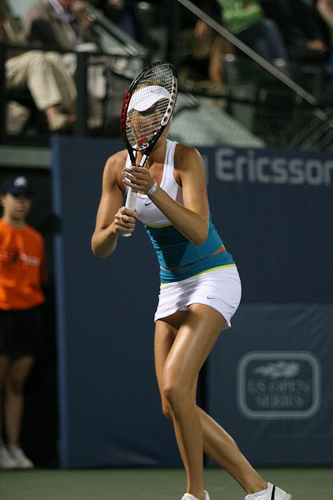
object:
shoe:
[244, 483, 293, 500]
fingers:
[115, 206, 140, 237]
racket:
[120, 59, 179, 238]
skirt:
[153, 265, 242, 331]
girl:
[0, 170, 50, 474]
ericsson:
[214, 147, 333, 188]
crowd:
[0, 0, 134, 143]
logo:
[236, 352, 323, 424]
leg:
[160, 303, 225, 495]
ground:
[301, 470, 323, 500]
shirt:
[124, 137, 236, 287]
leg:
[154, 284, 267, 494]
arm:
[144, 171, 210, 247]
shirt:
[0, 216, 47, 310]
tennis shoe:
[178, 489, 210, 498]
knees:
[162, 367, 181, 407]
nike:
[144, 200, 153, 208]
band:
[145, 179, 159, 197]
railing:
[0, 43, 332, 147]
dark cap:
[0, 173, 33, 196]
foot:
[244, 481, 293, 500]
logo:
[206, 295, 217, 299]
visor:
[128, 85, 173, 113]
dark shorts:
[0, 307, 40, 359]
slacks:
[0, 50, 77, 113]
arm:
[91, 170, 124, 258]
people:
[160, 0, 333, 108]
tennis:
[91, 76, 292, 500]